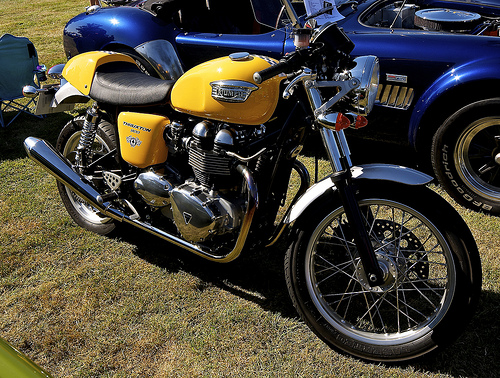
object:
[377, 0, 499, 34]
car engine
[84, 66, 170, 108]
seat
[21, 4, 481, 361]
motorcycle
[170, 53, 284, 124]
tank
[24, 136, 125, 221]
pipe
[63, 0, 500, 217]
car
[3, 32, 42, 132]
chair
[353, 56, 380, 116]
headlight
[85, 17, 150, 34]
blue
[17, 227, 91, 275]
grass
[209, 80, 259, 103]
panel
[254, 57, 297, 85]
handlebars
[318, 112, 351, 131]
turnsignals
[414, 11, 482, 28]
lid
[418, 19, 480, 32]
wheel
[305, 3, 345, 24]
paper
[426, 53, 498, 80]
covering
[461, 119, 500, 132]
covering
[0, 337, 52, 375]
surface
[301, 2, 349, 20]
wiper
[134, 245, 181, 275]
shadow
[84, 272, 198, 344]
ground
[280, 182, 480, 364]
tire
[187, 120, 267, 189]
engine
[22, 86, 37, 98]
light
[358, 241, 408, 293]
brake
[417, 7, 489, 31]
filter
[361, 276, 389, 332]
spokes